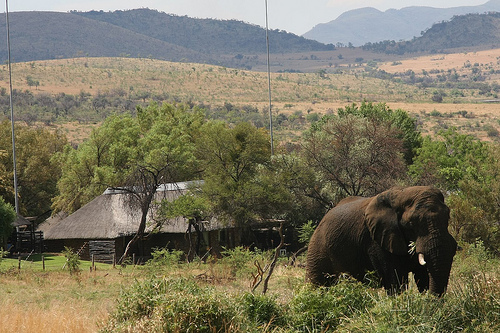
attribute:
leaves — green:
[48, 117, 152, 219]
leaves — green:
[135, 105, 219, 181]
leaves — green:
[183, 115, 278, 198]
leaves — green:
[401, 128, 498, 193]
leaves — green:
[439, 177, 498, 250]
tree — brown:
[48, 110, 201, 269]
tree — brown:
[280, 113, 410, 214]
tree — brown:
[1, 123, 71, 218]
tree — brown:
[405, 125, 499, 200]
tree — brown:
[443, 139, 499, 278]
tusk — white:
[415, 250, 429, 267]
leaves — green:
[305, 113, 403, 177]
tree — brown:
[298, 118, 410, 202]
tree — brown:
[255, 154, 326, 253]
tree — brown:
[410, 157, 447, 191]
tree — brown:
[444, 178, 499, 256]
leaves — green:
[87, 92, 235, 194]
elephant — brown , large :
[304, 178, 452, 293]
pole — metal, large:
[11, 7, 29, 279]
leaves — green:
[134, 120, 189, 161]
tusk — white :
[412, 245, 433, 269]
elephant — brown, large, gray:
[291, 180, 460, 307]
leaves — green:
[163, 295, 197, 316]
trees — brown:
[282, 102, 429, 197]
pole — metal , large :
[3, 44, 35, 251]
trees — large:
[49, 105, 236, 262]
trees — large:
[182, 108, 294, 253]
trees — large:
[251, 155, 330, 249]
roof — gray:
[43, 182, 271, 232]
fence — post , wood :
[98, 249, 150, 268]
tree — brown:
[292, 116, 406, 221]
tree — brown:
[199, 122, 277, 244]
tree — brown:
[246, 152, 332, 240]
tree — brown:
[0, 124, 78, 220]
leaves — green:
[314, 147, 376, 162]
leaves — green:
[76, 129, 150, 189]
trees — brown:
[41, 88, 279, 235]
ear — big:
[364, 181, 404, 264]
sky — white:
[0, 0, 495, 36]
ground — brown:
[2, 47, 497, 331]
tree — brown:
[172, 119, 275, 259]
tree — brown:
[240, 151, 344, 249]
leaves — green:
[321, 119, 403, 167]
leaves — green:
[318, 110, 399, 185]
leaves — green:
[213, 138, 263, 212]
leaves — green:
[264, 163, 317, 225]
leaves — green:
[5, 125, 75, 202]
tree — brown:
[304, 115, 407, 211]